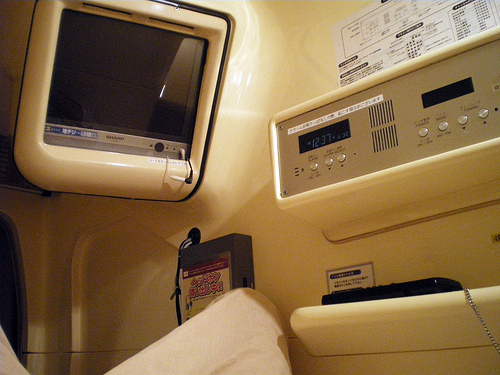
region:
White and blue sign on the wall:
[320, 263, 382, 294]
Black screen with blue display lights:
[292, 108, 356, 160]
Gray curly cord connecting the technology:
[461, 283, 498, 356]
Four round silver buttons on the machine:
[407, 105, 493, 143]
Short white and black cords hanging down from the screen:
[169, 143, 194, 188]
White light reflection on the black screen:
[155, 80, 171, 100]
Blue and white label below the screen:
[40, 120, 100, 142]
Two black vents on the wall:
[363, 98, 405, 153]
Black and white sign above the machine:
[328, 0, 498, 87]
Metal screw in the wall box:
[272, 120, 285, 134]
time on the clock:
[300, 122, 343, 148]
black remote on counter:
[320, 276, 465, 301]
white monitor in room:
[1, 0, 245, 203]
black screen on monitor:
[44, 13, 203, 146]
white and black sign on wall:
[338, 1, 499, 86]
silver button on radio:
[337, 151, 350, 165]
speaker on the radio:
[365, 101, 401, 125]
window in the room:
[2, 217, 32, 372]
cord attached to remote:
[466, 284, 498, 341]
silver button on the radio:
[414, 125, 432, 139]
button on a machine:
[306, 156, 323, 178]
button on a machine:
[320, 151, 337, 173]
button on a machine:
[333, 147, 356, 164]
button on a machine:
[414, 120, 433, 148]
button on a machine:
[434, 110, 453, 141]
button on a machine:
[454, 105, 470, 129]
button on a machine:
[476, 101, 488, 124]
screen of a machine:
[36, 16, 213, 155]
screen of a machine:
[291, 110, 353, 158]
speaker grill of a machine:
[363, 76, 405, 178]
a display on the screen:
[46, 14, 259, 179]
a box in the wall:
[153, 230, 254, 317]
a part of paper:
[308, 255, 403, 305]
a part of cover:
[314, 241, 386, 290]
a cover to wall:
[312, 240, 402, 297]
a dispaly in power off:
[58, 34, 210, 154]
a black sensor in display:
[143, 137, 174, 159]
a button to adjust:
[174, 141, 211, 174]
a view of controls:
[278, 78, 499, 222]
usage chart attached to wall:
[306, 15, 480, 82]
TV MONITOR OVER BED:
[23, 1, 205, 196]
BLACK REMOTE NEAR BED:
[313, 270, 465, 292]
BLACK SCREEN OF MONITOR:
[67, 16, 181, 155]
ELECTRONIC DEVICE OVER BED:
[266, 85, 494, 198]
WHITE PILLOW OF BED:
[113, 291, 246, 373]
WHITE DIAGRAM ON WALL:
[323, 24, 473, 66]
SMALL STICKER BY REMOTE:
[310, 262, 381, 288]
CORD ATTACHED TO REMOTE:
[467, 292, 492, 356]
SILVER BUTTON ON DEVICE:
[305, 151, 324, 176]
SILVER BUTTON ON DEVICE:
[480, 108, 488, 122]